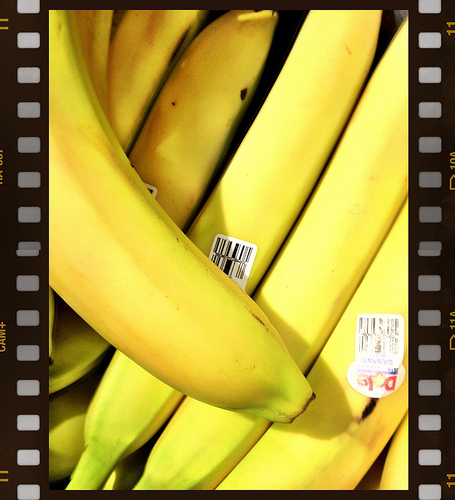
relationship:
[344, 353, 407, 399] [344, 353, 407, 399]
dole sticker in dole sticker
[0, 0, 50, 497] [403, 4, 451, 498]
film edging with film edging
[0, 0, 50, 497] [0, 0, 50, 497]
film edging with film edging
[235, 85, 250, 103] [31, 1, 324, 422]
brown spot on banana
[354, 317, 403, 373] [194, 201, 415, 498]
code on banana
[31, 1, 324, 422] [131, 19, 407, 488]
banana over banana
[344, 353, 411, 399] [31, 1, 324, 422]
dole sticker on banana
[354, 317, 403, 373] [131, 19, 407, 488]
code on banana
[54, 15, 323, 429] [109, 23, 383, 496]
banana lying across banana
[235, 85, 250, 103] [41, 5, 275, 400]
brown spot on corner of a banana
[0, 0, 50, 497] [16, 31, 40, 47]
film edging with rectangle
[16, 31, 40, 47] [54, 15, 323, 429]
rectangle surrounding a picture of banana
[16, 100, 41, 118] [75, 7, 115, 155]
rectangle surrounding a picture of banana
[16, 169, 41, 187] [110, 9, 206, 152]
rectangle surrounding a picture of banana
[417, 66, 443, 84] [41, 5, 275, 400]
rectangle surrounding a picture of banana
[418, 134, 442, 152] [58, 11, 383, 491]
rectangle surrounding a picture of banana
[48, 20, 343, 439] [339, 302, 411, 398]
banana with a dole sticker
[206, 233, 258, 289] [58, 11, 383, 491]
sticker on banana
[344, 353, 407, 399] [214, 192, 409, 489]
dole sticker of banana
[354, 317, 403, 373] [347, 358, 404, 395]
code on sticker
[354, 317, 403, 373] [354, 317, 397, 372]
code with code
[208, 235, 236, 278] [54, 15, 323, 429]
code on banana